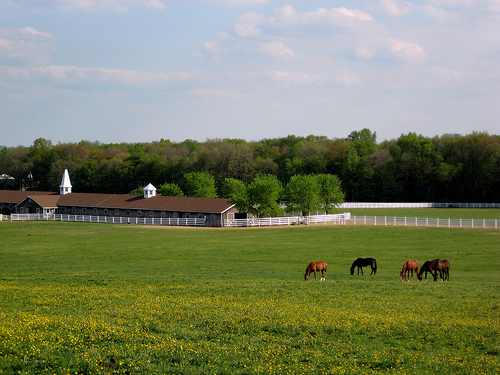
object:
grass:
[4, 229, 500, 375]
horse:
[303, 261, 327, 281]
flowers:
[87, 317, 94, 324]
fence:
[346, 215, 497, 226]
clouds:
[0, 22, 60, 55]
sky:
[0, 3, 497, 135]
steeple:
[59, 168, 73, 193]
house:
[0, 190, 58, 220]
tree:
[317, 174, 344, 214]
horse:
[399, 259, 419, 283]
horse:
[349, 257, 377, 275]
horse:
[418, 258, 452, 283]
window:
[160, 212, 166, 217]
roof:
[57, 192, 239, 214]